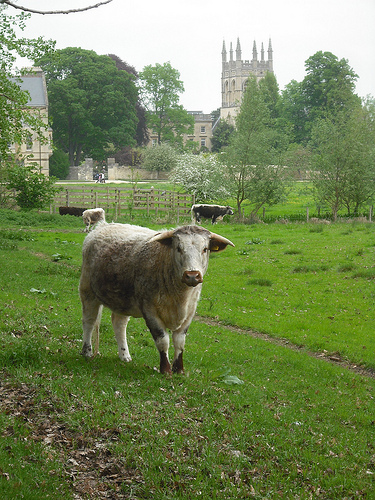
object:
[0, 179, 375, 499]
field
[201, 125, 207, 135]
window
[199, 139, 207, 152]
window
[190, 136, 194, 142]
window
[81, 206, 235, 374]
cow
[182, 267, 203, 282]
nose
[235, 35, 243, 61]
spires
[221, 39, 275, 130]
tower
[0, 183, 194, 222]
fence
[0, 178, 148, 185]
road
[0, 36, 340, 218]
tufts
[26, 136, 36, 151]
window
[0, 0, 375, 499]
scene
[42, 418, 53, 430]
leaves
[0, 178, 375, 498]
ground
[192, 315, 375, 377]
path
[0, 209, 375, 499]
grass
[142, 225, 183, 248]
horns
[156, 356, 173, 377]
feet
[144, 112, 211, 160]
building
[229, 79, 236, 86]
window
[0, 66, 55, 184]
building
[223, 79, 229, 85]
window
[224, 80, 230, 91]
openings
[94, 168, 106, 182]
people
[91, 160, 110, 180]
entry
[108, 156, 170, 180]
wall